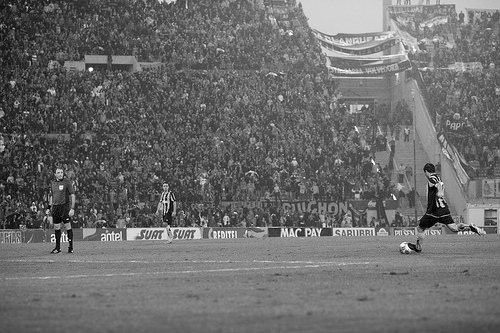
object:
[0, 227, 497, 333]
soccer pitch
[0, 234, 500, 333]
section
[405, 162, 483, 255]
soccer player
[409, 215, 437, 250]
leg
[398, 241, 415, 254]
ball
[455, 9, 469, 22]
spectators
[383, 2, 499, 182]
section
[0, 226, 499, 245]
advertising board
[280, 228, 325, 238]
writting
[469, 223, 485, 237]
foot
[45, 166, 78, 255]
referee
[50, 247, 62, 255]
foot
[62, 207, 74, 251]
leg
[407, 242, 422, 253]
foot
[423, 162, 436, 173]
hair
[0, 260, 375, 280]
lines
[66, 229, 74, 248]
sock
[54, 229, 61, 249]
sock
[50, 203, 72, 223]
shorts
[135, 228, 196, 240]
writting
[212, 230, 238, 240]
writting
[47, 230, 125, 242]
writting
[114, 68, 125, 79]
people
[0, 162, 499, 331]
soccer game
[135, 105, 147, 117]
people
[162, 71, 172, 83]
people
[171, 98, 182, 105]
people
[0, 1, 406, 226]
stands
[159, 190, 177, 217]
shirt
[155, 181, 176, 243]
person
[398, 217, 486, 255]
kicked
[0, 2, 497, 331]
stadium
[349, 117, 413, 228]
stairwell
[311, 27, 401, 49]
banner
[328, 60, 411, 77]
banner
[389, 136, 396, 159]
people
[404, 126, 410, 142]
people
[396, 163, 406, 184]
people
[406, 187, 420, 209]
people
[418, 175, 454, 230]
uniform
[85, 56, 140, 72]
entrance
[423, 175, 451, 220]
shirt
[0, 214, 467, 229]
border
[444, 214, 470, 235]
leg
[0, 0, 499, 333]
air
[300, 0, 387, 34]
sky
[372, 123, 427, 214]
rail